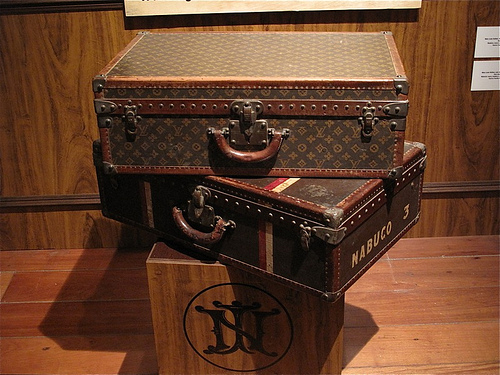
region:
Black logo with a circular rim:
[178, 278, 300, 373]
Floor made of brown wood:
[0, 235, 499, 373]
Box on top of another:
[88, 24, 428, 302]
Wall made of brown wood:
[0, 0, 499, 251]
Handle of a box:
[206, 125, 290, 165]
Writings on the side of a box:
[347, 202, 420, 271]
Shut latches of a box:
[121, 97, 379, 150]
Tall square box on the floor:
[128, 234, 367, 374]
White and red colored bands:
[253, 172, 300, 281]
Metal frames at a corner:
[391, 69, 411, 99]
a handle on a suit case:
[185, 112, 309, 189]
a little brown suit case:
[98, 7, 489, 178]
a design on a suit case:
[116, 35, 346, 165]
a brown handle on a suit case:
[204, 99, 306, 177]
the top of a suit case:
[132, 34, 324, 109]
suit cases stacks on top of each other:
[127, 45, 450, 300]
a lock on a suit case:
[188, 103, 345, 145]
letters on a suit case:
[339, 183, 463, 288]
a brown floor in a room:
[361, 255, 491, 348]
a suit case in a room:
[95, 40, 448, 288]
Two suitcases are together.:
[90, 30, 424, 303]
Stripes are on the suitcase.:
[257, 220, 272, 272]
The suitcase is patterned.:
[288, 125, 353, 165]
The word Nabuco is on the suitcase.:
[349, 220, 393, 269]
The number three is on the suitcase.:
[401, 203, 410, 219]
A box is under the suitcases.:
[149, 306, 341, 373]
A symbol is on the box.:
[197, 298, 280, 361]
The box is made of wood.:
[160, 270, 177, 350]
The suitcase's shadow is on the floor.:
[76, 253, 141, 350]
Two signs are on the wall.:
[473, 26, 498, 90]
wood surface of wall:
[2, 2, 497, 249]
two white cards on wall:
[470, 25, 498, 90]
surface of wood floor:
[0, 238, 497, 373]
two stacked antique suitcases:
[89, 29, 429, 301]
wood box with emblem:
[145, 238, 343, 373]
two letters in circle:
[183, 280, 295, 373]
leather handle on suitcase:
[207, 129, 288, 164]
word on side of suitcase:
[347, 219, 394, 269]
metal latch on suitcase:
[183, 183, 216, 230]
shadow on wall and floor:
[41, 219, 151, 373]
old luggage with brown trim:
[89, 27, 409, 178]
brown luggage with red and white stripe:
[88, 140, 427, 305]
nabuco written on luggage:
[351, 220, 393, 273]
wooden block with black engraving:
[145, 240, 346, 374]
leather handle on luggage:
[204, 123, 291, 168]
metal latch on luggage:
[120, 103, 143, 142]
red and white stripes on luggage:
[256, 215, 275, 277]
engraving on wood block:
[181, 278, 297, 371]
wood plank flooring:
[348, 233, 499, 367]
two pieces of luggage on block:
[88, 29, 430, 305]